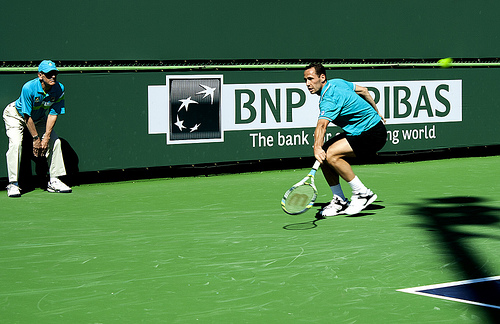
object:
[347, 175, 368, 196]
socks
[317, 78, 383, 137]
shirt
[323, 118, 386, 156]
shorts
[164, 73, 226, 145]
bank symbol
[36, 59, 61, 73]
hat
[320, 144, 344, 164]
knees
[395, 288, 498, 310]
lines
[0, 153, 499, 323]
court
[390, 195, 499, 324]
shadow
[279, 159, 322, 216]
tennis racket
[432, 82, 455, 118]
letter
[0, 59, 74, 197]
man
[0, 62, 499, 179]
wall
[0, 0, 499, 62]
wall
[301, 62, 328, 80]
black hair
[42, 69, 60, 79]
black shades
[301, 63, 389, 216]
man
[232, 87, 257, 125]
letter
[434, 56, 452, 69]
ball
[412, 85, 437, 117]
letter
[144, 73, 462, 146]
wall sign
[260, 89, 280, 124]
letter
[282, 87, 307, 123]
letter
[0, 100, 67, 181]
pants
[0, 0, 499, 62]
air